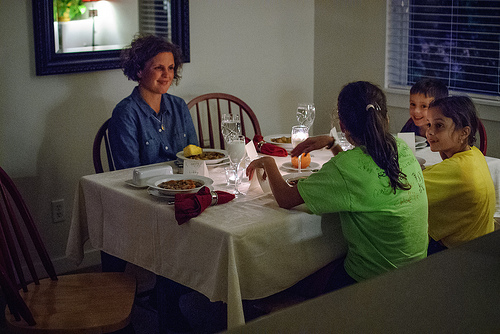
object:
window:
[384, 0, 499, 123]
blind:
[387, 1, 498, 101]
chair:
[0, 167, 141, 333]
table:
[62, 133, 499, 333]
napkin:
[173, 185, 235, 224]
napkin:
[241, 132, 288, 159]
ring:
[209, 188, 218, 205]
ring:
[255, 139, 266, 153]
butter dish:
[122, 163, 172, 188]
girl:
[246, 80, 430, 295]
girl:
[420, 95, 497, 256]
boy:
[398, 77, 450, 148]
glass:
[223, 133, 247, 184]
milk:
[227, 139, 246, 165]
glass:
[291, 124, 308, 153]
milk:
[291, 132, 308, 148]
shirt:
[297, 139, 429, 283]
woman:
[106, 32, 200, 169]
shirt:
[110, 84, 200, 168]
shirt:
[422, 147, 496, 248]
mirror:
[49, 0, 172, 56]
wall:
[0, 0, 316, 273]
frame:
[30, 1, 193, 80]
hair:
[336, 79, 411, 191]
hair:
[427, 93, 479, 146]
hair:
[408, 77, 451, 99]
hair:
[117, 34, 183, 86]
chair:
[92, 117, 118, 174]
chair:
[185, 92, 263, 148]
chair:
[401, 112, 490, 157]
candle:
[291, 151, 311, 168]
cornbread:
[181, 144, 201, 157]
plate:
[174, 147, 231, 163]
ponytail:
[362, 106, 410, 193]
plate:
[145, 173, 214, 198]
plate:
[265, 132, 301, 151]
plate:
[282, 171, 317, 190]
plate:
[411, 131, 427, 150]